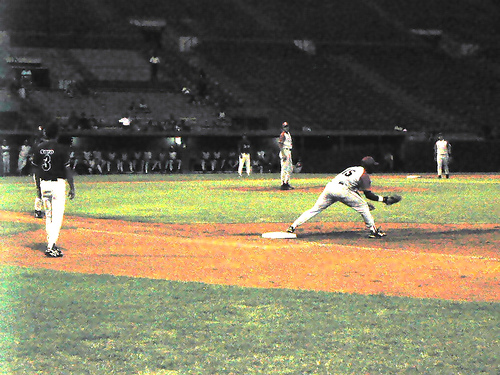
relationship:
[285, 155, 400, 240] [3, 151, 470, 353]
ball player on field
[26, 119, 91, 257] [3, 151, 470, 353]
person on field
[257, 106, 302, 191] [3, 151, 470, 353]
person on field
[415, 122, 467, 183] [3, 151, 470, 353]
person on field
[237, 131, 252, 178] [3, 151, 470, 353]
coach on field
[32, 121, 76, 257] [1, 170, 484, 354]
person on field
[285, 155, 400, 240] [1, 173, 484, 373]
ball player on field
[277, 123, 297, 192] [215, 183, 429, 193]
person on mound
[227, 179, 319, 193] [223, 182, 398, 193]
part apart mound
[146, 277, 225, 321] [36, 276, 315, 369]
grassy part in ball field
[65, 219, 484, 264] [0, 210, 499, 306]
baseline in dirt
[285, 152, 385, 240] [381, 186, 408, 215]
ball player has a glove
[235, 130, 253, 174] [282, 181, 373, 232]
coach wearing pants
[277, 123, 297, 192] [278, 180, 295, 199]
person on mound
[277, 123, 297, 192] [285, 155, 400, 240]
person watching ball player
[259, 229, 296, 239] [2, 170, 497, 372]
base on ground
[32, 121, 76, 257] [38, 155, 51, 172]
person wearing 3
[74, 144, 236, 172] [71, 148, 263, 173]
players on bench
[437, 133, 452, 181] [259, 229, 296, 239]
person on base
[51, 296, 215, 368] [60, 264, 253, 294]
grass around baseline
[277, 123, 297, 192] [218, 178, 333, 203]
person on mound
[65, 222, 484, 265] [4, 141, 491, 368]
baseline on field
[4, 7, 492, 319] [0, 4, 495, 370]
photo taken at a baseball stadium